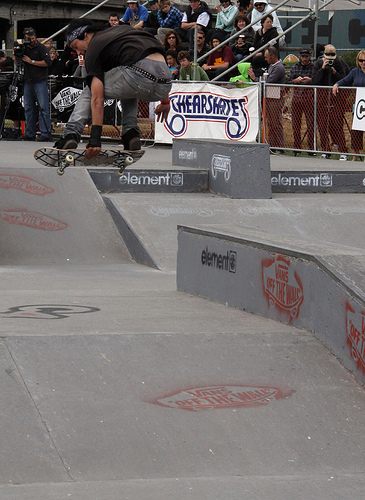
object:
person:
[49, 17, 175, 155]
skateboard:
[33, 147, 148, 176]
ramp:
[0, 333, 365, 500]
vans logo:
[143, 381, 284, 413]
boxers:
[134, 58, 173, 80]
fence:
[0, 69, 365, 158]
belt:
[127, 63, 176, 87]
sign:
[154, 84, 262, 144]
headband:
[65, 25, 88, 44]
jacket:
[229, 59, 255, 87]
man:
[21, 24, 52, 143]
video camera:
[13, 37, 35, 58]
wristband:
[86, 123, 104, 148]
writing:
[171, 92, 240, 115]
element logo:
[197, 245, 242, 273]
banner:
[51, 77, 123, 125]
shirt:
[288, 63, 317, 95]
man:
[289, 48, 317, 156]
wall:
[172, 134, 275, 201]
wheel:
[123, 156, 133, 167]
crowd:
[176, 45, 208, 81]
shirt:
[81, 26, 165, 80]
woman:
[312, 45, 350, 158]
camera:
[325, 55, 337, 69]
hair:
[66, 19, 93, 40]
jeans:
[62, 68, 173, 133]